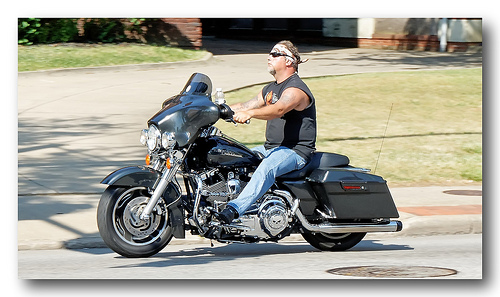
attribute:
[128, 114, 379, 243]
motorcycle — black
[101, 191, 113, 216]
tire — black, inflated, round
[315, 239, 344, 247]
tire — black, inflated, round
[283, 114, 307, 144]
shirt — black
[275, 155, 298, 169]
pants — blue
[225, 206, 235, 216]
shoe — black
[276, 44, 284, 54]
durag — brown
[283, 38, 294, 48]
hair — short, light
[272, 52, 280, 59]
glasses — black